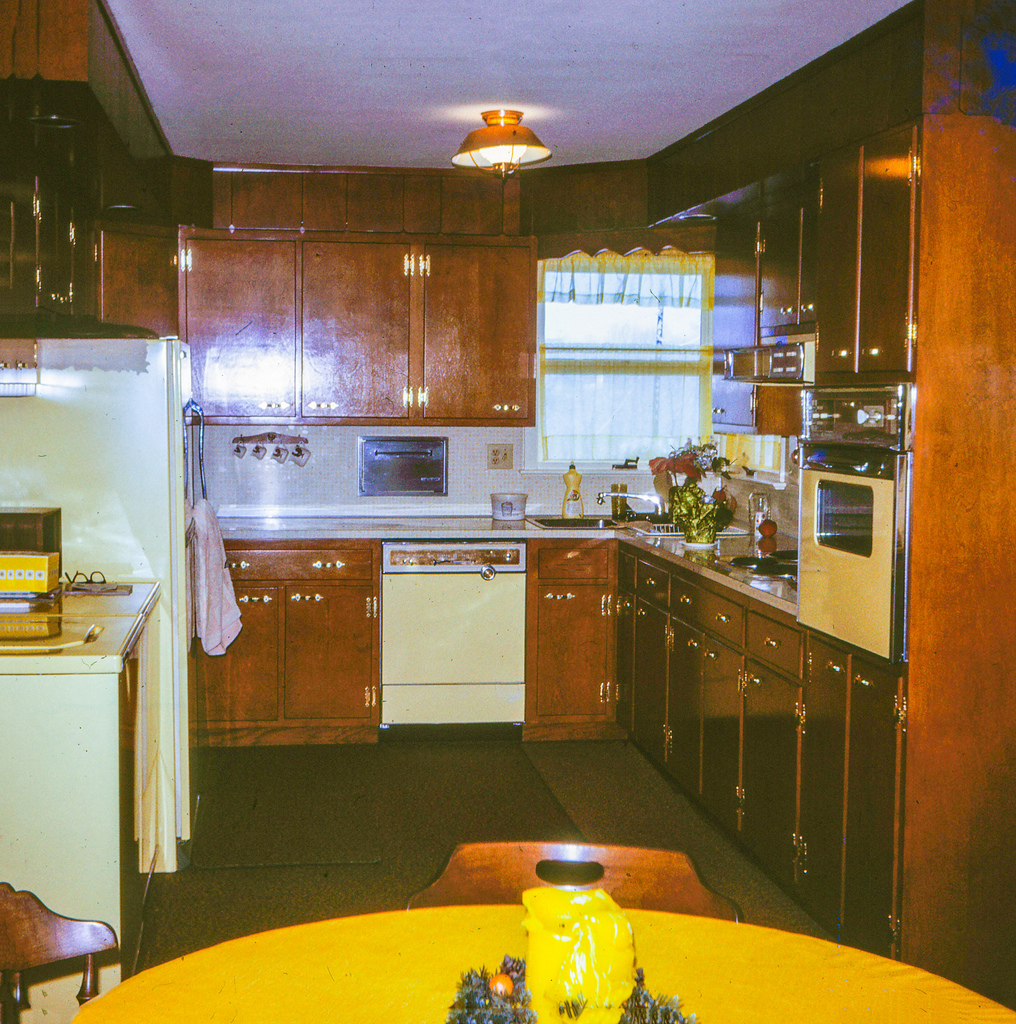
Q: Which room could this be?
A: It is a kitchen.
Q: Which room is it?
A: It is a kitchen.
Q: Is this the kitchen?
A: Yes, it is the kitchen.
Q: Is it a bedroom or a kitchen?
A: It is a kitchen.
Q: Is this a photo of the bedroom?
A: No, the picture is showing the kitchen.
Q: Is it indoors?
A: Yes, it is indoors.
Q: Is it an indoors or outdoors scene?
A: It is indoors.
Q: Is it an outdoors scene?
A: No, it is indoors.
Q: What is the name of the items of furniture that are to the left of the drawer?
A: The pieces of furniture are cabinets.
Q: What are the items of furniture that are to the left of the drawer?
A: The pieces of furniture are cabinets.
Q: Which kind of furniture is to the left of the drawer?
A: The pieces of furniture are cabinets.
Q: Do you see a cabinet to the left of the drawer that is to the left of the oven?
A: Yes, there are cabinets to the left of the drawer.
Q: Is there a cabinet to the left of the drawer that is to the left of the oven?
A: Yes, there are cabinets to the left of the drawer.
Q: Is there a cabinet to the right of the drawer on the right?
A: No, the cabinets are to the left of the drawer.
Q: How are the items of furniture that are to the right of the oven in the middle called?
A: The pieces of furniture are cabinets.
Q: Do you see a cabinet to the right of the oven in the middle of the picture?
A: Yes, there are cabinets to the right of the oven.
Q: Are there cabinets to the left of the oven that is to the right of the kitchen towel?
A: No, the cabinets are to the right of the oven.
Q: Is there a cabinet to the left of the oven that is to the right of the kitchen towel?
A: No, the cabinets are to the right of the oven.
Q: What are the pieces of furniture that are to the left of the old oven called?
A: The pieces of furniture are cabinets.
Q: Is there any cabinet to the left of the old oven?
A: Yes, there are cabinets to the left of the oven.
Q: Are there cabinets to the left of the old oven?
A: Yes, there are cabinets to the left of the oven.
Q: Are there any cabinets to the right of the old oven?
A: No, the cabinets are to the left of the oven.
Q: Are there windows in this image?
A: Yes, there is a window.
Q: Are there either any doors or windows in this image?
A: Yes, there is a window.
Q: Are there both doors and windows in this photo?
A: Yes, there are both a window and a door.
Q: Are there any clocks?
A: No, there are no clocks.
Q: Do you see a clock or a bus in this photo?
A: No, there are no clocks or buses.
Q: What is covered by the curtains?
A: The window is covered by the curtains.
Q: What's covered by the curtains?
A: The window is covered by the curtains.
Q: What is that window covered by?
A: The window is covered by the curtains.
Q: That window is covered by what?
A: The window is covered by the curtains.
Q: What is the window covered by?
A: The window is covered by the curtains.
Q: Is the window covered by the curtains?
A: Yes, the window is covered by the curtains.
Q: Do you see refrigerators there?
A: Yes, there is a refrigerator.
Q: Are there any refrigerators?
A: Yes, there is a refrigerator.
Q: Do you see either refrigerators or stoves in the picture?
A: Yes, there is a refrigerator.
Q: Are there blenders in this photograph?
A: No, there are no blenders.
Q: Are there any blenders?
A: No, there are no blenders.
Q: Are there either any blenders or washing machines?
A: No, there are no blenders or washing machines.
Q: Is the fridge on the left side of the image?
A: Yes, the fridge is on the left of the image.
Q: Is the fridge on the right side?
A: No, the fridge is on the left of the image.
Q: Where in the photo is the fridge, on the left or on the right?
A: The fridge is on the left of the image.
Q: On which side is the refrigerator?
A: The refrigerator is on the left of the image.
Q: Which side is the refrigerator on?
A: The refrigerator is on the left of the image.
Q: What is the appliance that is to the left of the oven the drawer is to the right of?
A: The appliance is a refrigerator.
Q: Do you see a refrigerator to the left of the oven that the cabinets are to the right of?
A: Yes, there is a refrigerator to the left of the oven.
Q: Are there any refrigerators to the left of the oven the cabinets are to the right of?
A: Yes, there is a refrigerator to the left of the oven.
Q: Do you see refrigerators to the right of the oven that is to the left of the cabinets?
A: No, the refrigerator is to the left of the oven.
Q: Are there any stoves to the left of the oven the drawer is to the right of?
A: No, there is a refrigerator to the left of the oven.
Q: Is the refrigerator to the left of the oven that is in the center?
A: Yes, the refrigerator is to the left of the oven.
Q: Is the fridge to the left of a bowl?
A: No, the fridge is to the left of the oven.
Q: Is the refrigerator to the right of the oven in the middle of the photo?
A: No, the refrigerator is to the left of the oven.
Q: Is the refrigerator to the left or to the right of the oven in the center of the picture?
A: The refrigerator is to the left of the oven.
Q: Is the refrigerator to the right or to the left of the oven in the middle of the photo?
A: The refrigerator is to the left of the oven.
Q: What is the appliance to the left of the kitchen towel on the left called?
A: The appliance is a refrigerator.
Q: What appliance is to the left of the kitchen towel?
A: The appliance is a refrigerator.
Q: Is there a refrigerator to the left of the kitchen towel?
A: Yes, there is a refrigerator to the left of the kitchen towel.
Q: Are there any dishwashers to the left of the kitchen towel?
A: No, there is a refrigerator to the left of the kitchen towel.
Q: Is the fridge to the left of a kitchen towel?
A: Yes, the fridge is to the left of a kitchen towel.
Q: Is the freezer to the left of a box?
A: No, the freezer is to the left of a kitchen towel.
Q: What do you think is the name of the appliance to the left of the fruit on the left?
A: The appliance is a refrigerator.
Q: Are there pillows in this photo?
A: No, there are no pillows.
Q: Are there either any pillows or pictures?
A: No, there are no pillows or pictures.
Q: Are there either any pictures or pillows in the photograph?
A: No, there are no pillows or pictures.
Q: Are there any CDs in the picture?
A: No, there are no cds.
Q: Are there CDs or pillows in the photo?
A: No, there are no CDs or pillows.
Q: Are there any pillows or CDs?
A: No, there are no CDs or pillows.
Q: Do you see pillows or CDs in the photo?
A: No, there are no CDs or pillows.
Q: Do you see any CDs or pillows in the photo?
A: No, there are no CDs or pillows.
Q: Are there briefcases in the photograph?
A: No, there are no briefcases.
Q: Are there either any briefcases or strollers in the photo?
A: No, there are no briefcases or strollers.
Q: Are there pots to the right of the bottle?
A: Yes, there are pots to the right of the bottle.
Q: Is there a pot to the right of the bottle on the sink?
A: Yes, there are pots to the right of the bottle.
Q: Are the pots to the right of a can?
A: No, the pots are to the right of the bottle.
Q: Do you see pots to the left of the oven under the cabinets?
A: Yes, there are pots to the left of the oven.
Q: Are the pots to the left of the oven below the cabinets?
A: Yes, the pots are to the left of the oven.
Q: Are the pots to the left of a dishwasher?
A: No, the pots are to the left of the oven.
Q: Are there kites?
A: No, there are no kites.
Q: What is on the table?
A: The candle is on the table.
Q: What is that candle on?
A: The candle is on the table.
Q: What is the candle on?
A: The candle is on the table.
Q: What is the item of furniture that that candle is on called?
A: The piece of furniture is a table.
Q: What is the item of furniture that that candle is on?
A: The piece of furniture is a table.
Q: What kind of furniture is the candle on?
A: The candle is on the table.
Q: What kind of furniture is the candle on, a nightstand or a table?
A: The candle is on a table.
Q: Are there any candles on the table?
A: Yes, there is a candle on the table.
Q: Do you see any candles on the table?
A: Yes, there is a candle on the table.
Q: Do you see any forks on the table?
A: No, there is a candle on the table.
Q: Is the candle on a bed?
A: No, the candle is on a table.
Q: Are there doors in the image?
A: Yes, there is a door.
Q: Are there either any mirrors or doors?
A: Yes, there is a door.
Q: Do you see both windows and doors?
A: Yes, there are both a door and windows.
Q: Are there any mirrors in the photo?
A: No, there are no mirrors.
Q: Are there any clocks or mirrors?
A: No, there are no mirrors or clocks.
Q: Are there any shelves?
A: No, there are no shelves.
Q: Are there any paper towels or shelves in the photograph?
A: No, there are no shelves or paper towels.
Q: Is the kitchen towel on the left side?
A: Yes, the kitchen towel is on the left of the image.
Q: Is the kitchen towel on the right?
A: No, the kitchen towel is on the left of the image.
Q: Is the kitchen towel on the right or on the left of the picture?
A: The kitchen towel is on the left of the image.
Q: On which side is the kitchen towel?
A: The kitchen towel is on the left of the image.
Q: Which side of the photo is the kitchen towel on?
A: The kitchen towel is on the left of the image.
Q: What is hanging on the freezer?
A: The kitchen towel is hanging on the freezer.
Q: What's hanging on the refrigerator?
A: The kitchen towel is hanging on the freezer.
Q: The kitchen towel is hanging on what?
A: The kitchen towel is hanging on the fridge.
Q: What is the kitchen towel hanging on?
A: The kitchen towel is hanging on the fridge.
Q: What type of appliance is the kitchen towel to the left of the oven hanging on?
A: The kitchen towel is hanging on the freezer.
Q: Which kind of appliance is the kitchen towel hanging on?
A: The kitchen towel is hanging on the freezer.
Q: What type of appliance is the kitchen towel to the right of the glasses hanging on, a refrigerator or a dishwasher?
A: The kitchen towel is hanging on a refrigerator.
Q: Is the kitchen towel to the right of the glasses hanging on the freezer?
A: Yes, the kitchen towel is hanging on the freezer.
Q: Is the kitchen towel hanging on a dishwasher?
A: No, the kitchen towel is hanging on the freezer.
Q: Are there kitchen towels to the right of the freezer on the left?
A: Yes, there is a kitchen towel to the right of the refrigerator.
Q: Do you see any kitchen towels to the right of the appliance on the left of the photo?
A: Yes, there is a kitchen towel to the right of the refrigerator.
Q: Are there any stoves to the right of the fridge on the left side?
A: No, there is a kitchen towel to the right of the freezer.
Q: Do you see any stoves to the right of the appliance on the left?
A: No, there is a kitchen towel to the right of the freezer.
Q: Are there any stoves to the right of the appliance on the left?
A: No, there is a kitchen towel to the right of the freezer.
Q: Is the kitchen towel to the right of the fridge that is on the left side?
A: Yes, the kitchen towel is to the right of the freezer.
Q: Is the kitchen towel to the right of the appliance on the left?
A: Yes, the kitchen towel is to the right of the freezer.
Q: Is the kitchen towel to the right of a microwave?
A: No, the kitchen towel is to the right of the freezer.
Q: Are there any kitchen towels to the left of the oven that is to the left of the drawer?
A: Yes, there is a kitchen towel to the left of the oven.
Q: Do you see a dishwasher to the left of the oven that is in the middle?
A: No, there is a kitchen towel to the left of the oven.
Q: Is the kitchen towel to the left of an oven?
A: Yes, the kitchen towel is to the left of an oven.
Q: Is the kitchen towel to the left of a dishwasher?
A: No, the kitchen towel is to the left of an oven.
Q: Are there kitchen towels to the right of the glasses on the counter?
A: Yes, there is a kitchen towel to the right of the glasses.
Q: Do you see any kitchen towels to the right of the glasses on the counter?
A: Yes, there is a kitchen towel to the right of the glasses.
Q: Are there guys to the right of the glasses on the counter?
A: No, there is a kitchen towel to the right of the glasses.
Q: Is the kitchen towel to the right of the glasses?
A: Yes, the kitchen towel is to the right of the glasses.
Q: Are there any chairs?
A: Yes, there is a chair.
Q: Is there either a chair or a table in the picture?
A: Yes, there is a chair.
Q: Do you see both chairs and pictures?
A: No, there is a chair but no pictures.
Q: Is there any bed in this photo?
A: No, there are no beds.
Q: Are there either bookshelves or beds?
A: No, there are no beds or bookshelves.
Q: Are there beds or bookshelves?
A: No, there are no beds or bookshelves.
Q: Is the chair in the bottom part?
A: Yes, the chair is in the bottom of the image.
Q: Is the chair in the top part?
A: No, the chair is in the bottom of the image.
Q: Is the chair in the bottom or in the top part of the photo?
A: The chair is in the bottom of the image.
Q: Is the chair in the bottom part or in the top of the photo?
A: The chair is in the bottom of the image.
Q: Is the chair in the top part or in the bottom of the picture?
A: The chair is in the bottom of the image.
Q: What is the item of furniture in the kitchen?
A: The piece of furniture is a chair.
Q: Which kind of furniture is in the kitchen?
A: The piece of furniture is a chair.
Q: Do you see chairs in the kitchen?
A: Yes, there is a chair in the kitchen.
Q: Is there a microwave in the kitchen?
A: No, there is a chair in the kitchen.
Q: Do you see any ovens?
A: Yes, there is an oven.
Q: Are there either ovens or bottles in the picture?
A: Yes, there is an oven.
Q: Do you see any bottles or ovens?
A: Yes, there is an oven.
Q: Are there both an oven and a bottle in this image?
A: Yes, there are both an oven and a bottle.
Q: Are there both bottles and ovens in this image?
A: Yes, there are both an oven and a bottle.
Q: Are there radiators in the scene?
A: No, there are no radiators.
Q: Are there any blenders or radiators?
A: No, there are no radiators or blenders.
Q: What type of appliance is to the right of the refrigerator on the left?
A: The appliance is an oven.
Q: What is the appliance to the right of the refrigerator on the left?
A: The appliance is an oven.